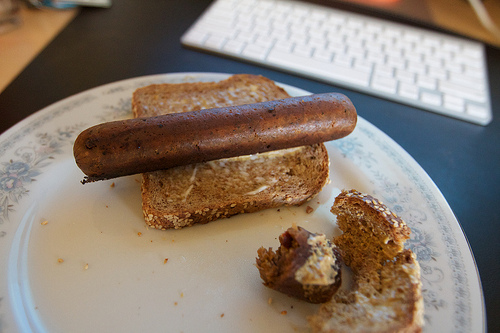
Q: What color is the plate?
A: White.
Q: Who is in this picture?
A: No one.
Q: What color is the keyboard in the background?
A: White.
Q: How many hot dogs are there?
A: One.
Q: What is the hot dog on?
A: Bread.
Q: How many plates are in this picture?
A: One.